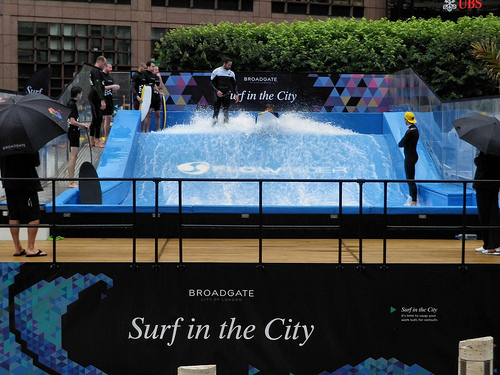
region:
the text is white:
[126, 300, 323, 362]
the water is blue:
[158, 112, 270, 199]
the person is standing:
[397, 109, 429, 194]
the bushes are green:
[225, 28, 305, 60]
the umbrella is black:
[11, 88, 73, 155]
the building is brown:
[10, 13, 169, 100]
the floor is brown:
[176, 233, 296, 264]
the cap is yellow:
[395, 110, 421, 132]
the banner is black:
[272, 265, 348, 315]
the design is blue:
[5, 258, 107, 373]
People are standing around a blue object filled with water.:
[0, 43, 496, 259]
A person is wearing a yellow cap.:
[397, 103, 417, 129]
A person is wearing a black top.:
[393, 120, 423, 157]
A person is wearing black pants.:
[393, 148, 424, 203]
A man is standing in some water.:
[202, 53, 239, 132]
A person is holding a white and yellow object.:
[132, 80, 154, 128]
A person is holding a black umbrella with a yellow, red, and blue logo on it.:
[0, 83, 77, 265]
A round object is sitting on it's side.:
[73, 156, 109, 214]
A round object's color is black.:
[69, 156, 111, 210]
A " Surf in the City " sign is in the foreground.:
[100, 261, 330, 357]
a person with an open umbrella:
[0, 90, 71, 253]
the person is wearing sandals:
[7, 211, 48, 262]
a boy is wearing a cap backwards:
[390, 110, 420, 205]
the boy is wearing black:
[395, 121, 423, 203]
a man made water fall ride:
[141, 105, 401, 211]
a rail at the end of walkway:
[7, 168, 479, 258]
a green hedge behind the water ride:
[155, 20, 496, 100]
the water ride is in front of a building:
[1, 5, 497, 255]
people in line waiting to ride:
[61, 55, 163, 175]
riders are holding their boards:
[128, 56, 170, 137]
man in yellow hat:
[390, 106, 426, 190]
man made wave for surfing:
[173, 105, 367, 169]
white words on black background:
[120, 307, 320, 357]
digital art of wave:
[9, 265, 102, 360]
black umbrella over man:
[2, 87, 72, 167]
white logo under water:
[177, 158, 354, 178]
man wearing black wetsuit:
[82, 55, 110, 145]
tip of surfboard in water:
[251, 107, 294, 133]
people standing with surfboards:
[135, 64, 172, 139]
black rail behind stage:
[175, 172, 356, 271]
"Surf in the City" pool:
[48, 62, 485, 229]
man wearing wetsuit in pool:
[192, 47, 242, 128]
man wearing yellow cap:
[388, 98, 443, 200]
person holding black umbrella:
[1, 83, 77, 268]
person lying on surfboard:
[253, 95, 290, 133]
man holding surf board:
[126, 51, 174, 133]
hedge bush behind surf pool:
[151, 10, 489, 106]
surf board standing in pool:
[67, 148, 114, 218]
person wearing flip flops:
[6, 229, 60, 281]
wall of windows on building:
[11, 12, 142, 117]